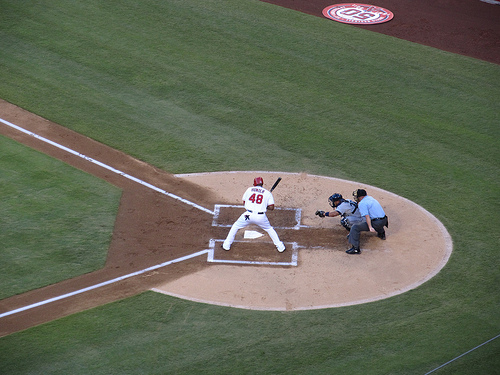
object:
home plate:
[243, 230, 265, 239]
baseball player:
[220, 177, 287, 254]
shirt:
[241, 185, 275, 213]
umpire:
[345, 188, 389, 254]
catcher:
[315, 193, 363, 239]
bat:
[269, 177, 282, 193]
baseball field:
[0, 0, 499, 374]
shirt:
[358, 195, 386, 223]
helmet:
[253, 177, 263, 187]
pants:
[222, 210, 285, 253]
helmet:
[328, 193, 343, 209]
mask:
[352, 189, 360, 203]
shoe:
[220, 243, 231, 251]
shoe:
[346, 247, 362, 255]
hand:
[368, 227, 376, 232]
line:
[1, 118, 215, 216]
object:
[322, 2, 394, 24]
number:
[249, 193, 256, 203]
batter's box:
[206, 239, 298, 267]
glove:
[315, 210, 326, 218]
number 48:
[249, 193, 263, 204]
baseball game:
[7, 8, 484, 368]